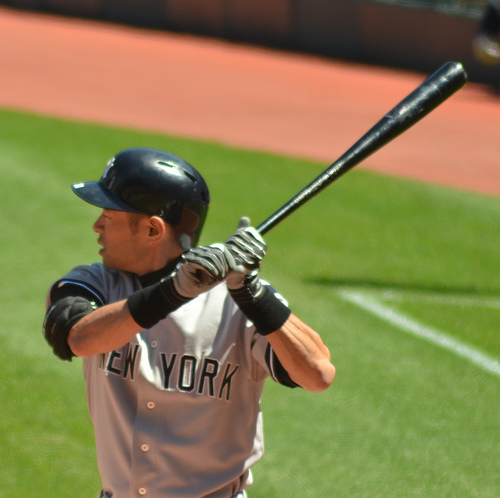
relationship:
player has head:
[44, 147, 335, 495] [91, 146, 211, 274]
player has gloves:
[44, 147, 335, 495] [170, 214, 266, 303]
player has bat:
[44, 147, 335, 495] [201, 60, 467, 287]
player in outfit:
[44, 147, 335, 495] [43, 260, 297, 496]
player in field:
[44, 147, 335, 495] [0, 10, 495, 496]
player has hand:
[44, 147, 335, 495] [227, 215, 334, 392]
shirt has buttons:
[47, 260, 299, 497] [138, 338, 157, 496]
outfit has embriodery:
[43, 260, 297, 496] [98, 341, 240, 403]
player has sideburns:
[44, 147, 335, 495] [136, 215, 153, 244]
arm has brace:
[47, 244, 235, 362] [45, 284, 100, 362]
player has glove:
[44, 147, 335, 495] [225, 215, 267, 305]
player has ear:
[44, 147, 335, 495] [147, 217, 165, 246]